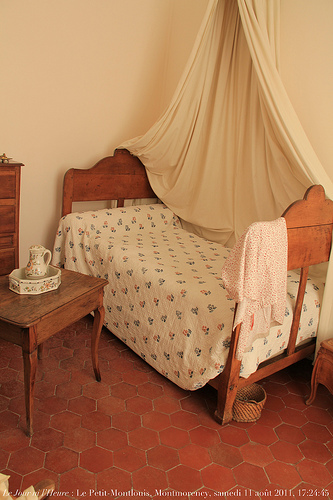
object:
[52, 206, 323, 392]
bedding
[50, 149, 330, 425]
bed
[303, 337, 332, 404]
side table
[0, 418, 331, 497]
floor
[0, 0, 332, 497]
bedroom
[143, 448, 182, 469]
shapes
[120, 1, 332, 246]
curtains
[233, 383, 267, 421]
basket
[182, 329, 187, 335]
flower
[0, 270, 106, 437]
table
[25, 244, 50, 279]
pitcher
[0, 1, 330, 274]
wall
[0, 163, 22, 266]
dresser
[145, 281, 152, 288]
flower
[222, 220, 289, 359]
blanket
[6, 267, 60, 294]
bowl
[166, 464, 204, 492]
tile